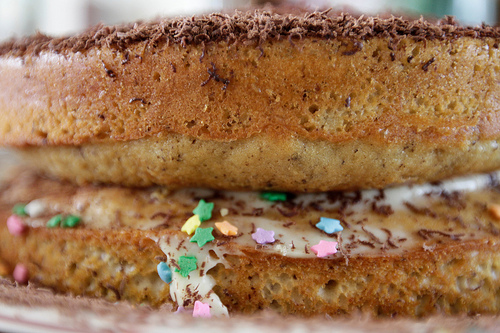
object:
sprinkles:
[173, 255, 198, 278]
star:
[264, 190, 287, 202]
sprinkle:
[249, 221, 280, 247]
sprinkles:
[214, 220, 240, 237]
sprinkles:
[252, 228, 276, 243]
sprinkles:
[7, 214, 28, 233]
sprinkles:
[189, 227, 217, 247]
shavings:
[101, 20, 174, 49]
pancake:
[0, 2, 500, 317]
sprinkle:
[188, 199, 215, 217]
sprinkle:
[187, 223, 214, 251]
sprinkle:
[174, 254, 199, 279]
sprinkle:
[44, 214, 81, 232]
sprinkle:
[47, 209, 85, 231]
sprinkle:
[260, 192, 286, 202]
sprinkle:
[314, 215, 343, 237]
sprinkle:
[157, 259, 174, 284]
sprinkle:
[308, 235, 342, 259]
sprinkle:
[190, 299, 212, 318]